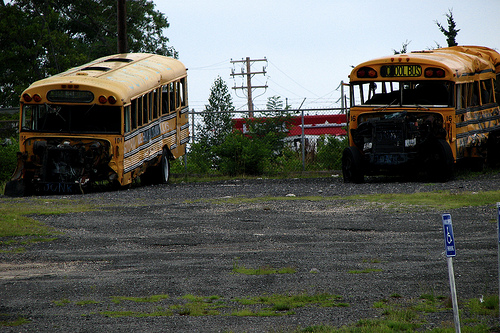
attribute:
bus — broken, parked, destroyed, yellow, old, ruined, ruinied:
[342, 58, 454, 182]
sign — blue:
[431, 205, 467, 267]